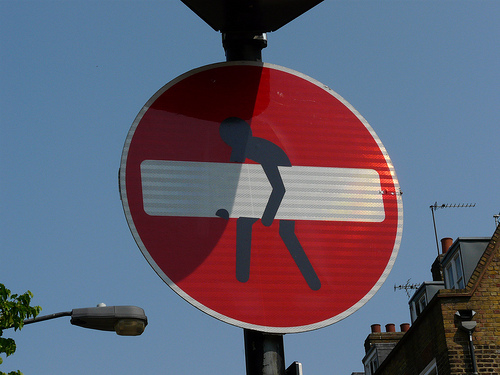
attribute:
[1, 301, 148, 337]
light — grey, gray, off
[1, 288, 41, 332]
leaves — green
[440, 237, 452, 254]
chimney — brown, round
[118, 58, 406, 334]
sign — red, circle, white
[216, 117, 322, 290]
human — gray, black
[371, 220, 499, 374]
building — brick, light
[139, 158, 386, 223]
rectangle — white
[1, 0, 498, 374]
sky — blue, open